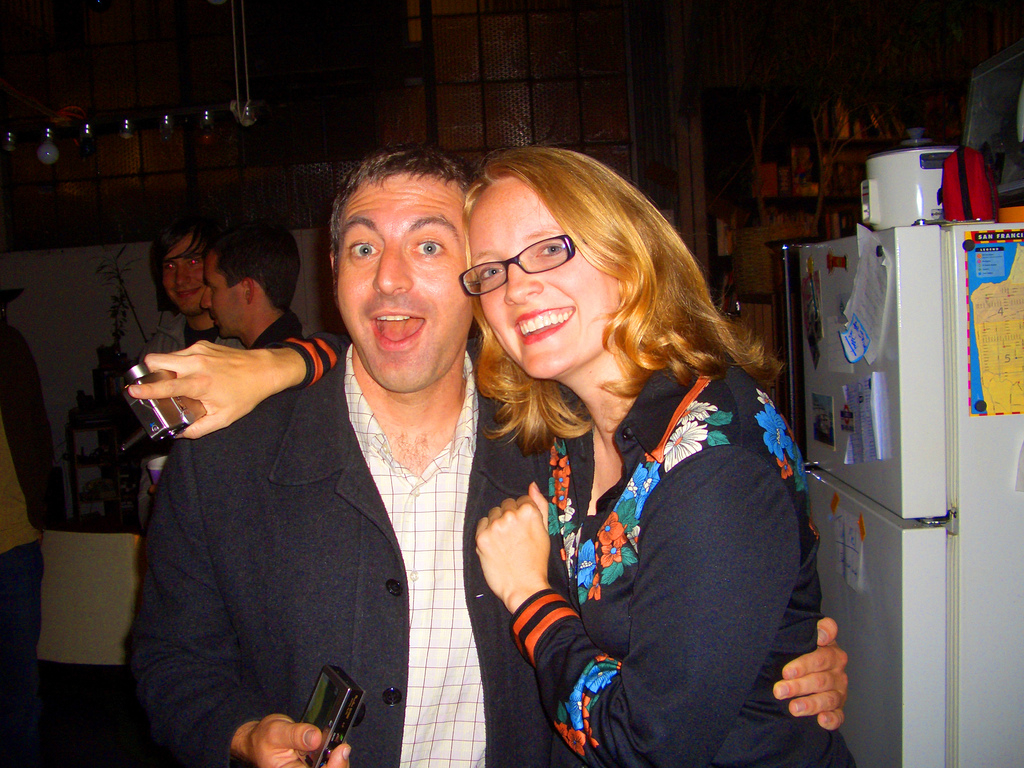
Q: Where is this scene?
A: By the fridge.